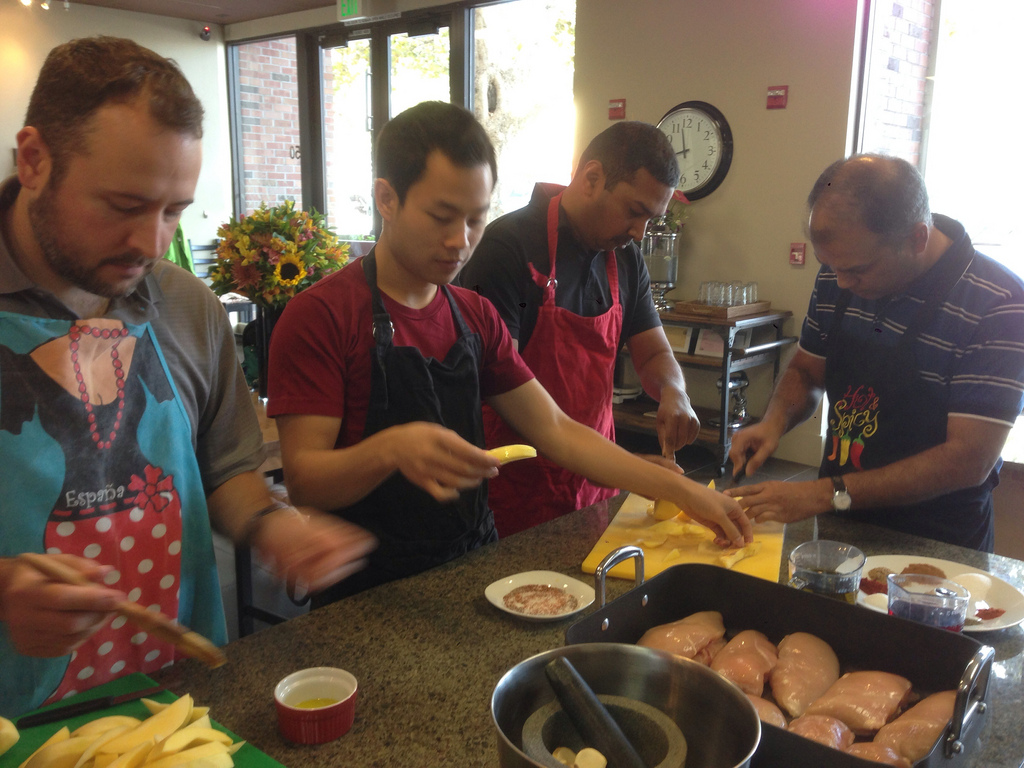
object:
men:
[0, 34, 1024, 715]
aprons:
[0, 190, 997, 717]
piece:
[770, 631, 838, 718]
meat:
[799, 671, 914, 736]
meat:
[848, 689, 963, 763]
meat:
[709, 630, 778, 699]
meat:
[841, 743, 910, 767]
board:
[581, 480, 784, 583]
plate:
[484, 570, 596, 622]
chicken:
[635, 611, 958, 768]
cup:
[274, 668, 357, 744]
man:
[266, 100, 751, 610]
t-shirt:
[266, 258, 534, 447]